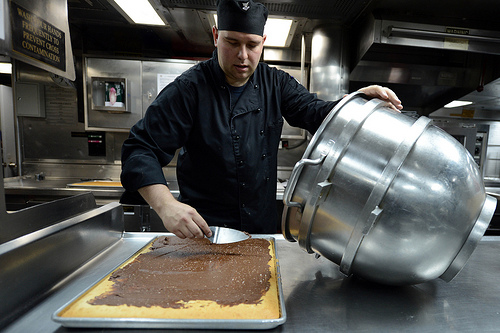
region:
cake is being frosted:
[40, 200, 295, 330]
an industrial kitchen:
[15, 1, 490, 329]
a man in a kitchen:
[54, 4, 479, 331]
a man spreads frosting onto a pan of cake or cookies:
[63, 4, 490, 331]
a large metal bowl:
[257, 69, 491, 329]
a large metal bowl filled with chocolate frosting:
[273, 59, 498, 331]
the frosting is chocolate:
[90, 161, 282, 330]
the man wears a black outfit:
[97, 1, 377, 263]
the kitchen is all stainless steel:
[16, 6, 493, 331]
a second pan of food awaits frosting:
[64, 169, 187, 216]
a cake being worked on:
[61, 194, 279, 331]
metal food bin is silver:
[258, 76, 491, 305]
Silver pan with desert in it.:
[72, 245, 304, 330]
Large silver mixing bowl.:
[254, 107, 478, 318]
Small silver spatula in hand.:
[182, 202, 255, 282]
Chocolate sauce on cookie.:
[127, 235, 264, 329]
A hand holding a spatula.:
[115, 180, 236, 277]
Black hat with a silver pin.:
[102, 8, 299, 71]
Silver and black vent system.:
[318, 14, 476, 91]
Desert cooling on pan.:
[51, 148, 121, 223]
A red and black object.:
[72, 127, 115, 161]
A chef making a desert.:
[17, 30, 361, 315]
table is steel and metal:
[293, 276, 423, 321]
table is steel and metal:
[276, 227, 426, 320]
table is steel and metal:
[314, 255, 428, 297]